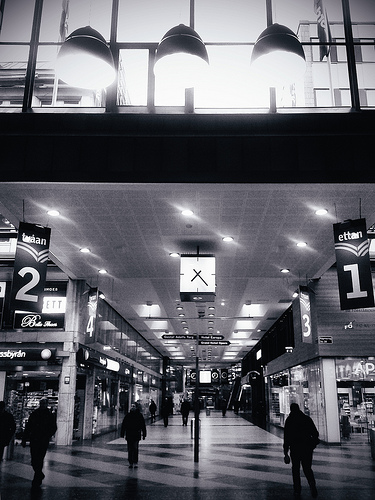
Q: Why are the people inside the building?
A: To shop.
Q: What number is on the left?
A: 2.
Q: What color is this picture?
A: Black and white.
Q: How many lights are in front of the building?
A: 3.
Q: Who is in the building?
A: Shoppers.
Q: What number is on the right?
A: 1.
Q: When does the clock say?
A: 7:25.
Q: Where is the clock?
A: On the ceiling.